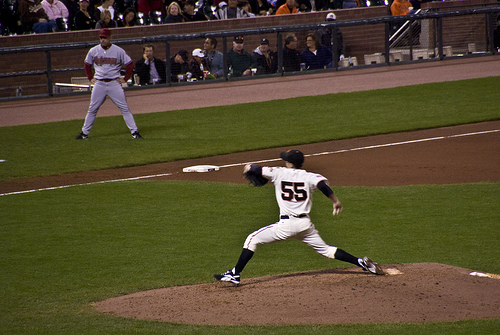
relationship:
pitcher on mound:
[213, 149, 384, 287] [93, 260, 499, 327]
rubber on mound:
[381, 266, 403, 277] [93, 260, 499, 327]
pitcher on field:
[213, 149, 384, 287] [0, 53, 497, 332]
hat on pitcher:
[279, 146, 305, 168] [213, 149, 384, 287]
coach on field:
[75, 26, 143, 140] [0, 53, 497, 332]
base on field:
[181, 163, 219, 173] [0, 53, 497, 332]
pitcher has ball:
[213, 149, 384, 287] [330, 206, 342, 216]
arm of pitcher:
[306, 172, 337, 204] [213, 149, 384, 287]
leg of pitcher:
[231, 224, 284, 271] [213, 149, 384, 287]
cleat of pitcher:
[211, 271, 242, 286] [213, 149, 384, 287]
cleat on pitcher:
[211, 271, 242, 286] [213, 149, 384, 287]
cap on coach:
[98, 23, 111, 38] [75, 26, 143, 140]